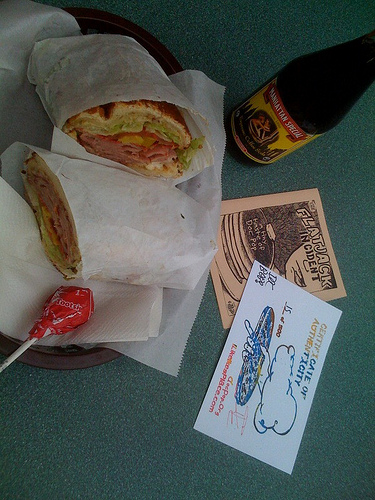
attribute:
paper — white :
[0, 0, 227, 377]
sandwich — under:
[64, 99, 204, 177]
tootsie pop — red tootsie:
[3, 281, 94, 396]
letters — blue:
[285, 346, 318, 403]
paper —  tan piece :
[198, 187, 351, 313]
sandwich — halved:
[19, 13, 255, 319]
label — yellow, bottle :
[228, 95, 305, 149]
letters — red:
[206, 341, 240, 416]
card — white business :
[193, 259, 343, 475]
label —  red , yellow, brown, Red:
[230, 80, 325, 165]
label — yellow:
[240, 94, 305, 158]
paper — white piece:
[191, 258, 342, 474]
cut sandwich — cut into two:
[10, 37, 214, 290]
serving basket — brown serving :
[0, 6, 199, 366]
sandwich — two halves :
[91, 110, 174, 166]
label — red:
[228, 75, 320, 166]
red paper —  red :
[24, 280, 101, 347]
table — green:
[219, 15, 310, 59]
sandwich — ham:
[24, 36, 217, 291]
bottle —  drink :
[236, 27, 371, 177]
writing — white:
[267, 84, 305, 140]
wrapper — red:
[28, 285, 94, 339]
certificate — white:
[193, 257, 343, 473]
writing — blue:
[291, 348, 316, 399]